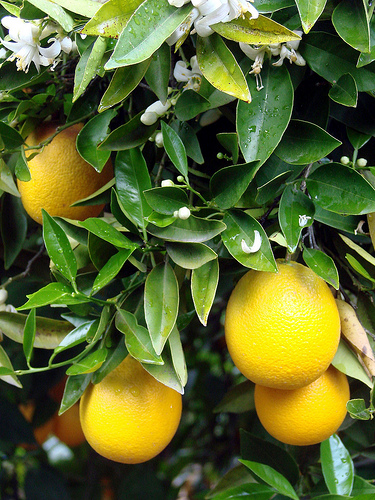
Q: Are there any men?
A: No, there are no men.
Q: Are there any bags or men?
A: No, there are no men or bags.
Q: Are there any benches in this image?
A: No, there are no benches.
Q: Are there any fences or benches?
A: No, there are no benches or fences.